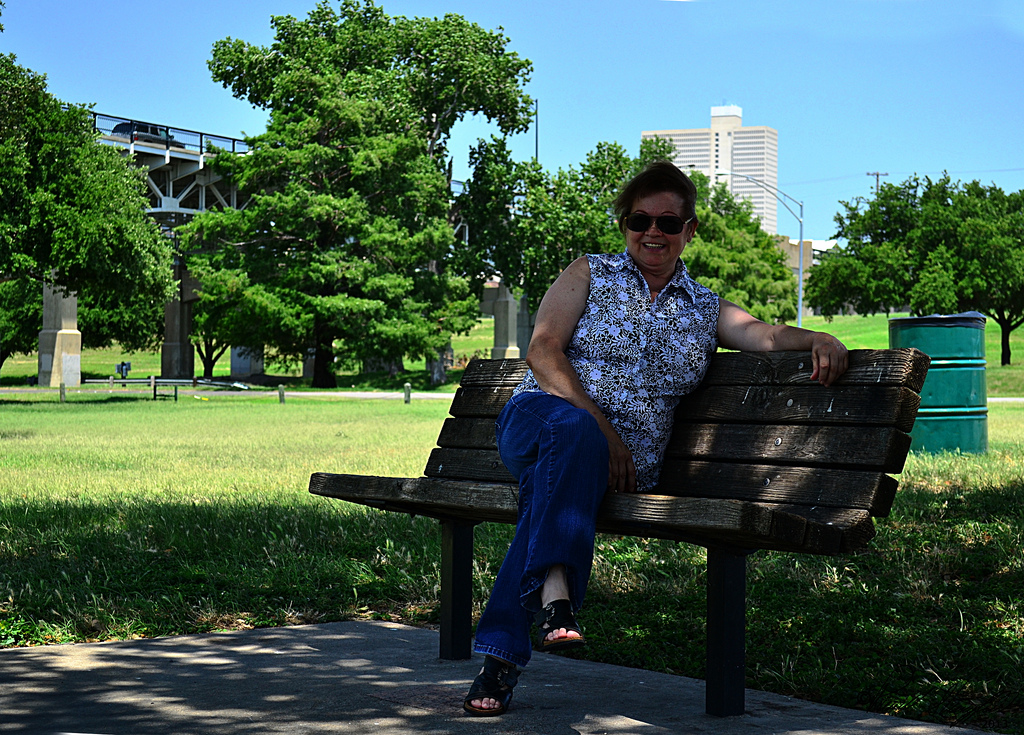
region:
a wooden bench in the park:
[305, 338, 944, 722]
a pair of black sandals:
[452, 589, 598, 720]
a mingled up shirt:
[508, 244, 727, 475]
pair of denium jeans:
[464, 385, 639, 677]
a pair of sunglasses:
[612, 206, 693, 244]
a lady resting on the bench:
[454, 149, 850, 723]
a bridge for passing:
[8, 80, 531, 390]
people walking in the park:
[114, 333, 489, 387]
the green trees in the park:
[2, 6, 1023, 386]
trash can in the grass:
[878, 284, 1019, 461]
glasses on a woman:
[616, 197, 697, 244]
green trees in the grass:
[791, 153, 1022, 378]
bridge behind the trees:
[42, 79, 547, 267]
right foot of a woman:
[537, 592, 602, 659]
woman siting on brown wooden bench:
[506, 133, 786, 683]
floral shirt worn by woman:
[590, 253, 707, 437]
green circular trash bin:
[906, 306, 1002, 446]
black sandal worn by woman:
[517, 572, 590, 656]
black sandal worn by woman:
[444, 645, 520, 718]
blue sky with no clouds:
[599, 22, 689, 65]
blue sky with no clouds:
[775, 19, 859, 80]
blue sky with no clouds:
[842, 43, 1011, 142]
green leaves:
[289, 124, 388, 226]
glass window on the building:
[702, 122, 716, 138]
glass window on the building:
[712, 128, 719, 139]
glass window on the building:
[708, 137, 721, 148]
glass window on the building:
[710, 144, 714, 155]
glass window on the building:
[710, 147, 715, 155]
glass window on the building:
[712, 159, 719, 172]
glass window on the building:
[743, 141, 751, 149]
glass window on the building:
[700, 145, 707, 152]